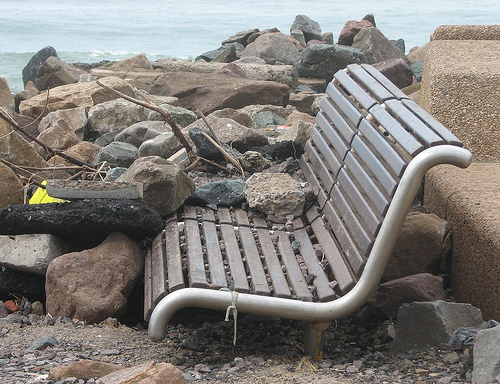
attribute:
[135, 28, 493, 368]
bench — park, wooden, metal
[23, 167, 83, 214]
debris — yellow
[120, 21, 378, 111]
boulders — large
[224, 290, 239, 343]
rope — scrap of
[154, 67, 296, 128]
boulder — large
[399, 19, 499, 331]
stone wall — pebble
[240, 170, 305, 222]
rock — large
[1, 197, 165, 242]
asphalt — black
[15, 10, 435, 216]
rocks — large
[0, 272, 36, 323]
object — red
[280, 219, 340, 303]
rocks — smaller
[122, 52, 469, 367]
bench — metal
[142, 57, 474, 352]
bench — metal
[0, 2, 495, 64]
sea water — calm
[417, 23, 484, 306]
block — concrete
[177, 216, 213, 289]
bar — wooden